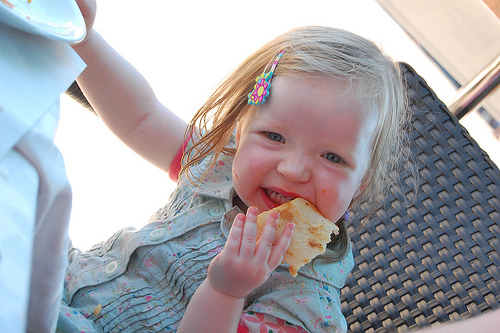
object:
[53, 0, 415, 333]
girl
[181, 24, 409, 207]
blonde hair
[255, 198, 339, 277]
food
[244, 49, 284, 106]
flower band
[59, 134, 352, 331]
blouse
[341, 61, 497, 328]
chair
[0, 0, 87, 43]
plate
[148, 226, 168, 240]
buttons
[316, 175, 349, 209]
cheek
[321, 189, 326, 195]
sauce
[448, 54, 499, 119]
pole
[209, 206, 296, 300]
hand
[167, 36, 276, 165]
strands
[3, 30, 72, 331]
table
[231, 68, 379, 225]
face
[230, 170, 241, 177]
sauce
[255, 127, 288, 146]
eye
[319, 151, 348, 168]
eye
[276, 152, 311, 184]
nose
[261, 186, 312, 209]
mouth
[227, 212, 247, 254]
finger